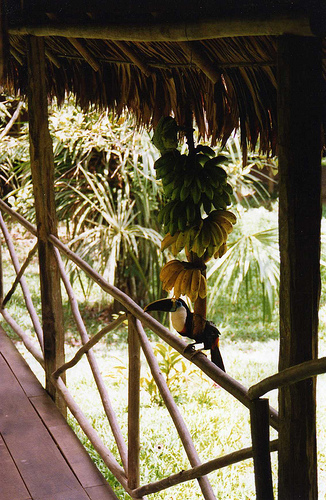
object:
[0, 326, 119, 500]
floor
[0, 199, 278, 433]
rail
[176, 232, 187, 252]
bananas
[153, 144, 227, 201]
bunch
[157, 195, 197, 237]
bunch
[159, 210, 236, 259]
bunch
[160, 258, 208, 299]
bunch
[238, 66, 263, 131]
leaves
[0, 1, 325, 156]
roofing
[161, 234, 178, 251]
banana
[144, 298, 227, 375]
toucan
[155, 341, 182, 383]
plant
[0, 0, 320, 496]
tent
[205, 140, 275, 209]
plant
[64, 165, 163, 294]
plant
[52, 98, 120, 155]
plant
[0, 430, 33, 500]
planks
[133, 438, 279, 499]
stick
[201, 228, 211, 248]
banana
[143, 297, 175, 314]
horn bill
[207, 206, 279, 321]
palm tree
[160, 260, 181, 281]
banana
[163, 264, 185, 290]
banana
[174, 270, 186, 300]
banana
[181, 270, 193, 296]
banana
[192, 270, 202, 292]
banana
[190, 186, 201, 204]
banana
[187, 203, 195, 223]
banana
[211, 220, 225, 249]
banana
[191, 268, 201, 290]
banana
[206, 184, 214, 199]
banana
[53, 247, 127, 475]
x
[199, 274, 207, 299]
bananas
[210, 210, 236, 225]
banana